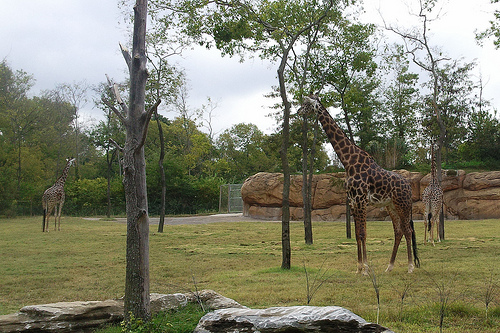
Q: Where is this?
A: This is at the forest.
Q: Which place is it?
A: It is a forest.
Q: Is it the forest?
A: Yes, it is the forest.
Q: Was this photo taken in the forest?
A: Yes, it was taken in the forest.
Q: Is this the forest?
A: Yes, it is the forest.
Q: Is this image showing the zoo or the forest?
A: It is showing the forest.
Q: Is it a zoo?
A: No, it is a forest.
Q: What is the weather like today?
A: It is cloudy.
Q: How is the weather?
A: It is cloudy.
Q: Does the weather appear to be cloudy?
A: Yes, it is cloudy.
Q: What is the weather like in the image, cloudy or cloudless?
A: It is cloudy.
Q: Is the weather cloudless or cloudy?
A: It is cloudy.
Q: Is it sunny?
A: No, it is cloudy.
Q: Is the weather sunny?
A: No, it is cloudy.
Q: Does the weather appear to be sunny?
A: No, it is cloudy.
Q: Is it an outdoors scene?
A: Yes, it is outdoors.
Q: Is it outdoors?
A: Yes, it is outdoors.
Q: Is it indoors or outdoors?
A: It is outdoors.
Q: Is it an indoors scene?
A: No, it is outdoors.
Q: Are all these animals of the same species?
A: Yes, all the animals are giraffes.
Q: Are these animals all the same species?
A: Yes, all the animals are giraffes.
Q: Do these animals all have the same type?
A: Yes, all the animals are giraffes.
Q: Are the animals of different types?
A: No, all the animals are giraffes.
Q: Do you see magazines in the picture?
A: No, there are no magazines.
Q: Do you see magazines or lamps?
A: No, there are no magazines or lamps.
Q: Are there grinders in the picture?
A: No, there are no grinders.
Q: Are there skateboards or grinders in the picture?
A: No, there are no grinders or skateboards.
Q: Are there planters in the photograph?
A: No, there are no planters.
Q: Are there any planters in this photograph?
A: No, there are no planters.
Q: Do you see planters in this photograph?
A: No, there are no planters.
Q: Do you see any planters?
A: No, there are no planters.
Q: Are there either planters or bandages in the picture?
A: No, there are no planters or bandages.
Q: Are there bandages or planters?
A: No, there are no planters or bandages.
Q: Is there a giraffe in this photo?
A: Yes, there is a giraffe.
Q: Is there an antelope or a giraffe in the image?
A: Yes, there is a giraffe.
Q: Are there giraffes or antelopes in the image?
A: Yes, there is a giraffe.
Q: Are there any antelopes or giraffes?
A: Yes, there is a giraffe.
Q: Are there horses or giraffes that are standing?
A: Yes, the giraffe is standing.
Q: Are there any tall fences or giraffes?
A: Yes, there is a tall giraffe.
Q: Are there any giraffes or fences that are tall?
A: Yes, the giraffe is tall.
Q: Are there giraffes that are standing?
A: Yes, there is a giraffe that is standing.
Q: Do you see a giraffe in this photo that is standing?
A: Yes, there is a giraffe that is standing.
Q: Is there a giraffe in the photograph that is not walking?
A: Yes, there is a giraffe that is standing.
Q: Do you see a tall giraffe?
A: Yes, there is a tall giraffe.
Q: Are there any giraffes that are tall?
A: Yes, there is a giraffe that is tall.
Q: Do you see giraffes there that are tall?
A: Yes, there is a giraffe that is tall.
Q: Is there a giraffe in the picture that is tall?
A: Yes, there is a giraffe that is tall.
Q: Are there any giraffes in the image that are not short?
A: Yes, there is a tall giraffe.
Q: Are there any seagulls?
A: No, there are no seagulls.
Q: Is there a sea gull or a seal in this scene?
A: No, there are no seagulls or seals.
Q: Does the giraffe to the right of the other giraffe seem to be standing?
A: Yes, the giraffe is standing.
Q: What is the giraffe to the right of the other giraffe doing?
A: The giraffe is standing.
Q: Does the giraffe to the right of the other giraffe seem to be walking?
A: No, the giraffe is standing.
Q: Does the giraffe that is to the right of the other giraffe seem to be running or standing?
A: The giraffe is standing.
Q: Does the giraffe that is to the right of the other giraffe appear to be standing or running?
A: The giraffe is standing.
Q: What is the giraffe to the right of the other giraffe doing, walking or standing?
A: The giraffe is standing.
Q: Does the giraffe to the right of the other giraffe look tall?
A: Yes, the giraffe is tall.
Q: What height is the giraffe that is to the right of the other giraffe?
A: The giraffe is tall.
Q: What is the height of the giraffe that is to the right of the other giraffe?
A: The giraffe is tall.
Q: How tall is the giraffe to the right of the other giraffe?
A: The giraffe is tall.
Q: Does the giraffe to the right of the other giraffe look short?
A: No, the giraffe is tall.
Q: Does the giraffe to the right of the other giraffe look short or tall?
A: The giraffe is tall.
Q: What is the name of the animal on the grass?
A: The animal is a giraffe.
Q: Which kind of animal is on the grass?
A: The animal is a giraffe.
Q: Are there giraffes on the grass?
A: Yes, there is a giraffe on the grass.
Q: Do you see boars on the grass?
A: No, there is a giraffe on the grass.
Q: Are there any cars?
A: No, there are no cars.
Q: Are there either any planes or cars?
A: No, there are no cars or planes.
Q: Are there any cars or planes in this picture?
A: No, there are no cars or planes.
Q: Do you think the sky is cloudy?
A: Yes, the sky is cloudy.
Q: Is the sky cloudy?
A: Yes, the sky is cloudy.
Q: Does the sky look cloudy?
A: Yes, the sky is cloudy.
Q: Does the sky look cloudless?
A: No, the sky is cloudy.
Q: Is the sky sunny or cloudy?
A: The sky is cloudy.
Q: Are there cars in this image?
A: No, there are no cars.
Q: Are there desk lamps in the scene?
A: No, there are no desk lamps.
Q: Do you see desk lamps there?
A: No, there are no desk lamps.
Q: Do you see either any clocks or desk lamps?
A: No, there are no desk lamps or clocks.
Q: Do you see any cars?
A: No, there are no cars.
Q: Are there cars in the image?
A: No, there are no cars.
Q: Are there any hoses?
A: No, there are no hoses.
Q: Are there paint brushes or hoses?
A: No, there are no hoses or paint brushes.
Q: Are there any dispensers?
A: No, there are no dispensers.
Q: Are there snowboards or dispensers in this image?
A: No, there are no dispensers or snowboards.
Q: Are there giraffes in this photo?
A: Yes, there is a giraffe.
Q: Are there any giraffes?
A: Yes, there is a giraffe.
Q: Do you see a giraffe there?
A: Yes, there is a giraffe.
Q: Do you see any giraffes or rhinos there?
A: Yes, there is a giraffe.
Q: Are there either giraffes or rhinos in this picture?
A: Yes, there is a giraffe.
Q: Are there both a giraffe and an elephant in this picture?
A: No, there is a giraffe but no elephants.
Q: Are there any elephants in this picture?
A: No, there are no elephants.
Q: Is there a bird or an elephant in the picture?
A: No, there are no elephants or birds.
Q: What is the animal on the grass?
A: The animal is a giraffe.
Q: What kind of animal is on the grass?
A: The animal is a giraffe.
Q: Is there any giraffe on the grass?
A: Yes, there is a giraffe on the grass.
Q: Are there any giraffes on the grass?
A: Yes, there is a giraffe on the grass.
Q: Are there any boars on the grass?
A: No, there is a giraffe on the grass.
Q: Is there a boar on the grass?
A: No, there is a giraffe on the grass.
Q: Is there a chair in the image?
A: No, there are no chairs.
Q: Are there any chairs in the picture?
A: No, there are no chairs.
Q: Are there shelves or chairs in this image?
A: No, there are no chairs or shelves.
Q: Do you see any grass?
A: Yes, there is grass.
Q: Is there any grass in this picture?
A: Yes, there is grass.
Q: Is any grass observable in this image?
A: Yes, there is grass.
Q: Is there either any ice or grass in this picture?
A: Yes, there is grass.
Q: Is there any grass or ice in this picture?
A: Yes, there is grass.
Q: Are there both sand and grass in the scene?
A: No, there is grass but no sand.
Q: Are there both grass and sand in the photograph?
A: No, there is grass but no sand.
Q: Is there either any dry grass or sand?
A: Yes, there is dry grass.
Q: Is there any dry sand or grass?
A: Yes, there is dry grass.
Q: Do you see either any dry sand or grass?
A: Yes, there is dry grass.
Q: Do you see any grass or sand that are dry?
A: Yes, the grass is dry.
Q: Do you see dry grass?
A: Yes, there is dry grass.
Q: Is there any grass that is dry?
A: Yes, there is grass that is dry.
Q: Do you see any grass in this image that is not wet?
A: Yes, there is dry grass.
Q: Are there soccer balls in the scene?
A: No, there are no soccer balls.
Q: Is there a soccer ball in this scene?
A: No, there are no soccer balls.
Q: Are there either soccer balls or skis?
A: No, there are no soccer balls or skis.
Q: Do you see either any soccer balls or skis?
A: No, there are no soccer balls or skis.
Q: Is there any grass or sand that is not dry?
A: No, there is grass but it is dry.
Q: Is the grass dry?
A: Yes, the grass is dry.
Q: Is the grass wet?
A: No, the grass is dry.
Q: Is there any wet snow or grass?
A: No, there is grass but it is dry.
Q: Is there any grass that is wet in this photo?
A: No, there is grass but it is dry.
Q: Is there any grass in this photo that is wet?
A: No, there is grass but it is dry.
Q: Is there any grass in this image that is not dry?
A: No, there is grass but it is dry.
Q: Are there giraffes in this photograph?
A: Yes, there is a giraffe.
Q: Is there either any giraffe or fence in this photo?
A: Yes, there is a giraffe.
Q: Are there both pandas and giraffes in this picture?
A: No, there is a giraffe but no pandas.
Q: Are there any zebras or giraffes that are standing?
A: Yes, the giraffe is standing.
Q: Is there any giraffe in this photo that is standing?
A: Yes, there is a giraffe that is standing.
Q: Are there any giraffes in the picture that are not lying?
A: Yes, there is a giraffe that is standing.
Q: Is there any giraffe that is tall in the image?
A: Yes, there is a tall giraffe.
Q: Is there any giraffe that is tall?
A: Yes, there is a giraffe that is tall.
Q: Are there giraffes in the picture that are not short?
A: Yes, there is a tall giraffe.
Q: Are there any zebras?
A: No, there are no zebras.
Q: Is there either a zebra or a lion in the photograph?
A: No, there are no zebras or lions.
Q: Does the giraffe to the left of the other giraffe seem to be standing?
A: Yes, the giraffe is standing.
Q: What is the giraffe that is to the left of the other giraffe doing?
A: The giraffe is standing.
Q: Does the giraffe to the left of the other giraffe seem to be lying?
A: No, the giraffe is standing.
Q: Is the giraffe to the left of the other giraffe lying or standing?
A: The giraffe is standing.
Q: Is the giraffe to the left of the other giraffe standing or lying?
A: The giraffe is standing.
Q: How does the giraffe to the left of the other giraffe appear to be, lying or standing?
A: The giraffe is standing.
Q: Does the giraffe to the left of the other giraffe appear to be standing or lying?
A: The giraffe is standing.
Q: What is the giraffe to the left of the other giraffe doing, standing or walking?
A: The giraffe is standing.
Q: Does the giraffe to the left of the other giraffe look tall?
A: Yes, the giraffe is tall.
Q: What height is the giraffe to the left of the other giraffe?
A: The giraffe is tall.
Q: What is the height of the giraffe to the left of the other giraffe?
A: The giraffe is tall.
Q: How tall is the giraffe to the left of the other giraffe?
A: The giraffe is tall.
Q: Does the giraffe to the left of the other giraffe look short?
A: No, the giraffe is tall.